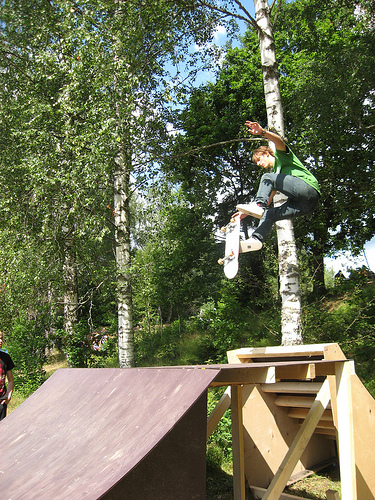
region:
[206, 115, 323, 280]
skateboarder high in mid-jump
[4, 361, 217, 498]
brown wooden skate board ramp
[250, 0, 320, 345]
long narrow white birch trunk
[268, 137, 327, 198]
men's green tee shirt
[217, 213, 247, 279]
bottom side of white skateboard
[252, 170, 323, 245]
men's blue denim pants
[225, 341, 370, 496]
A light brown skateboard ramp.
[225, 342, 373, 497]
The lighter brown wood skateboard ramp.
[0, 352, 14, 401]
Black shirt on a boy.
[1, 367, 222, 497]
A maroon wood ramp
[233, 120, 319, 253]
Skateboarder in the air in a green shirt.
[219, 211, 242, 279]
A white skateboard with orange wheels.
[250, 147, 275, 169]
Head of a skater in the air.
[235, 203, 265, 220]
A man's left white shoe.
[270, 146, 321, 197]
Green shirt on a guy.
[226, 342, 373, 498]
A light brown ramp.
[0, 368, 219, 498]
Maroon curved ramp board.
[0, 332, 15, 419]
A boy standing in a black shirt.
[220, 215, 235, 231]
Two top orange skateboard wheels.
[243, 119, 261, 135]
Left hand in the air on a green shirt guy.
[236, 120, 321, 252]
A man in the air with a green shirt on.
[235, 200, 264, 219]
Left white shoe in the air on a skater.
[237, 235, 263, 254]
A man's right white shoe.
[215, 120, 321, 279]
Boy in the air on a skateboard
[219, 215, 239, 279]
Skateboard in the air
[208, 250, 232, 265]
Wheels on a skateboard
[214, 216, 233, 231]
Two wheels on a skateboard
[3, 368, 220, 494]
Wooden ramp for a skateboard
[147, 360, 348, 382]
Wooden platform near a ramp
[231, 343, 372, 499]
Wooden steps for a skateboard ramp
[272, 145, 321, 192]
Green t-shirt on a skateboarder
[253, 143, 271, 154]
Brown hair on a skateboarder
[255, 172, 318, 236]
Blue jeans on a boy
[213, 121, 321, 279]
Skateboarder up in the air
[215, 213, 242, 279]
A skateboard under a boy in the air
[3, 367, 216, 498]
A skateboard ramp under a skateboarder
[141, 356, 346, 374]
A platform beside a skateboard ramp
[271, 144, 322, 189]
A green shirt on a skateboarder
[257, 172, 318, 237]
A pair of jeans on a boy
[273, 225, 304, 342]
A white birch tree trunk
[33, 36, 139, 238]
Green leaves on a birch tree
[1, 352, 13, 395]
A black t-shirt on a boy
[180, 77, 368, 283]
this is a man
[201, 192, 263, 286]
this is a skateboard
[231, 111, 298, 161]
man has arm extended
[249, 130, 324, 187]
man wearing a green shirt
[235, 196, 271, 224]
The man is wearing white sneakers.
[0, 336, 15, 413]
A man is standing watching the man skateboarding.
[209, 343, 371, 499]
The stairs going up to the ramp are made of wood.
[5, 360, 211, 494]
The skateboarding ramp is painted purple.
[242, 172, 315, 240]
The man is wearing a pair of blue pants.